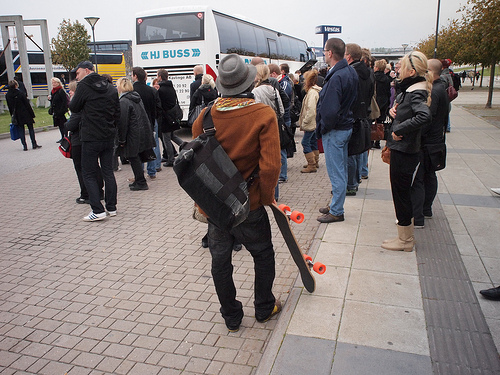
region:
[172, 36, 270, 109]
man has grey cap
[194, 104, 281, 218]
man has brown coat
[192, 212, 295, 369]
man has dark pants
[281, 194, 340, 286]
board has orange wheels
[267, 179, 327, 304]
man is holding board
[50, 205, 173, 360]
sidewalk is light brown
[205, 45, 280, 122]
man wearing grey hat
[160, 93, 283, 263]
man holding black back pack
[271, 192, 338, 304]
black and orange skate board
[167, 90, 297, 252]
man wearing brown sweater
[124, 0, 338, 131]
white bus parked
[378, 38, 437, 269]
lady dressed in black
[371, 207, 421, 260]
lady wearing tan boots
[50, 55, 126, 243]
man dressed in black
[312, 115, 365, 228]
man wearing blue jeans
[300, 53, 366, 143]
man wearing blue jacket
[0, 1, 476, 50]
cloud cover in daytime sky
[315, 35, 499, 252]
people standing on sidewalk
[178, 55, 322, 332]
back of man holding vertical skateboard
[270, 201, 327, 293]
skateboard with four orange wheels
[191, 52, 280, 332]
man with gray hat on head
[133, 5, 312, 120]
back and side of bus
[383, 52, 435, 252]
woman with blonde hair in braid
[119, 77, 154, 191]
woman in hooded jacket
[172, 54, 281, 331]
man with bag strap on shoulder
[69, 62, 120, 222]
man with stripes on sneakers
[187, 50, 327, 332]
man holding a skateboard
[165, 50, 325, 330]
man carrying a bag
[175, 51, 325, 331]
man wearing a gray hat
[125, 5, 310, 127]
a white charter bus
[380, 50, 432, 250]
woman wearing a headband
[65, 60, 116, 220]
man wearing a black cap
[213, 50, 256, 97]
Hat on man's head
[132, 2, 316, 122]
white bus at the corner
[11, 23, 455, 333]
Many people standing around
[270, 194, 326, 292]
Skateboard with orange wheels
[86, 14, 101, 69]
Street lamp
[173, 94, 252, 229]
Backpack on man's back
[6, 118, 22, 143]
Blue bag in person's hand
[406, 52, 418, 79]
Headband around woman's hair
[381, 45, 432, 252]
woman wearing black jacket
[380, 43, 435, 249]
woman wearing black pants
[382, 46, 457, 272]
woman wearing brown boots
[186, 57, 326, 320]
man holding a skate board